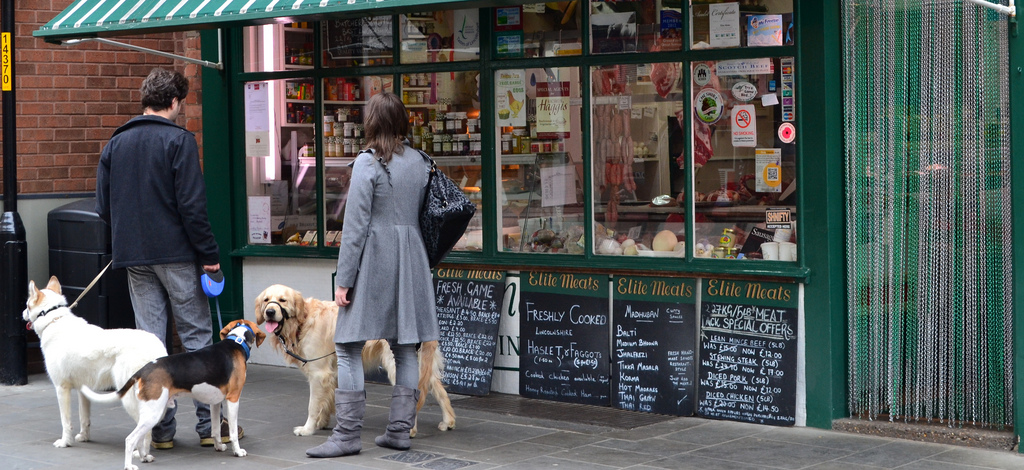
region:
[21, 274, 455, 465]
the dogs are standing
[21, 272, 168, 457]
the dog is white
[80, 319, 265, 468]
the dog is multi colored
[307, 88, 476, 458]
the woman carrying the large bag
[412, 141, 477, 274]
the large bag is black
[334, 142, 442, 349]
the long coat is gray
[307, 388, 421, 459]
the boots are gray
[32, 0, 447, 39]
the awning is green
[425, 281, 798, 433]
the black boards have writing in white chalk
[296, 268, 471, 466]
legs of the woman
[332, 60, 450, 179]
head of the woman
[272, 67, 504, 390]
woman in a gray outfit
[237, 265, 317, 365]
head of a dog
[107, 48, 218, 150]
head of a man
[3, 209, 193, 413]
white dog next to man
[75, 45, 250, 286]
man with a brown jacket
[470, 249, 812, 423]
writing on the building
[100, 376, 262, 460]
legs of the dog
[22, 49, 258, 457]
Man walking two dogs.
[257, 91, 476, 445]
Woman walking one dog.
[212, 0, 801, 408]
Front of a butcher shop.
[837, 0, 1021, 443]
A beaded entryway.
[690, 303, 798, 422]
A chalkboard with white writing.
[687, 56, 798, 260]
Window of a building.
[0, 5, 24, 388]
A black metal pole.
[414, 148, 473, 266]
A large black shoulder bag.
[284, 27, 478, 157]
Items on shelves in shop.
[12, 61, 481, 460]
a couple walking three dogs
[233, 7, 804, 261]
front window of butcher shop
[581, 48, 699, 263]
sausages hanging behind window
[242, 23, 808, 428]
chalkboards under storefront window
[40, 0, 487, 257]
green and white awning above window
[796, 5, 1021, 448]
doorway has beaded curtain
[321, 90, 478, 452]
woman carries large black purse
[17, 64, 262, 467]
man is holding leashes for two dogs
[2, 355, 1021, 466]
sidewalk is grey stone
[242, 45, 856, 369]
this is a cafe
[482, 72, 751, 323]
the window frames are green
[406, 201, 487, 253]
the purse is black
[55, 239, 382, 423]
there are three dogs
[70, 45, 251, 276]
the man is looking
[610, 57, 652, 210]
a window on the building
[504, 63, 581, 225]
a window on the building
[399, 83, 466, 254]
a window on the building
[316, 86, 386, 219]
a window on the building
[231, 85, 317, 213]
a window on the building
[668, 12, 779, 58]
a window on the building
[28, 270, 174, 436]
white dog beside the man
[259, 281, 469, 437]
blonde dog beside the woman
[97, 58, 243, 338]
man wearing black coat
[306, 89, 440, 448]
woman wearing long gray coat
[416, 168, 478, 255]
black bag the woman is carrying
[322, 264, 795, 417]
black chalkboard with white writing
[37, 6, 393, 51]
green awning on the building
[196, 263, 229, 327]
blue leash the man is holding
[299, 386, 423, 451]
gray boots the woman is wearing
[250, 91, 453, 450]
Woman walking dog on the street.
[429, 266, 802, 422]
Menu displayed on chalkboard.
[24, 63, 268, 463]
Men holds two leashed dogs.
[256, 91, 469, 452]
Woman wearing a gray coat.